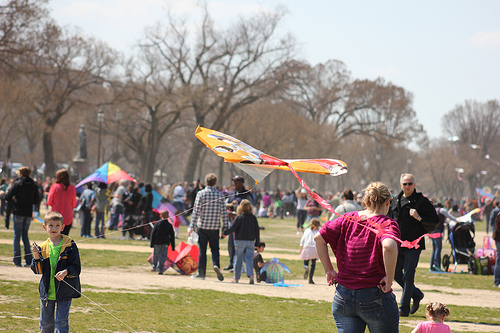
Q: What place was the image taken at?
A: It was taken at the park.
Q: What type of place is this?
A: It is a park.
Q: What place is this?
A: It is a park.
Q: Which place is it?
A: It is a park.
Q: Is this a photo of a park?
A: Yes, it is showing a park.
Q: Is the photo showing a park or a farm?
A: It is showing a park.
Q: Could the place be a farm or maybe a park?
A: It is a park.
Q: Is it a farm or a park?
A: It is a park.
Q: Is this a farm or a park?
A: It is a park.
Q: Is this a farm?
A: No, it is a park.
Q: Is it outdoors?
A: Yes, it is outdoors.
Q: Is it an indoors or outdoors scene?
A: It is outdoors.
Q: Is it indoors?
A: No, it is outdoors.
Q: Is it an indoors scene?
A: No, it is outdoors.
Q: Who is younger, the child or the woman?
A: The child is younger than the woman.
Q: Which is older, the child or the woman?
A: The woman is older than the child.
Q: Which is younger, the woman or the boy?
A: The boy is younger than the woman.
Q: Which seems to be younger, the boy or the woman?
A: The boy is younger than the woman.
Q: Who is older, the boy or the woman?
A: The woman is older than the boy.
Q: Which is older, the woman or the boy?
A: The woman is older than the boy.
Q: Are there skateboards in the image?
A: No, there are no skateboards.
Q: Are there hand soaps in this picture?
A: No, there are no hand soaps.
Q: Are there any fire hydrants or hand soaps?
A: No, there are no hand soaps or fire hydrants.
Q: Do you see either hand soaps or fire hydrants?
A: No, there are no hand soaps or fire hydrants.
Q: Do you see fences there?
A: No, there are no fences.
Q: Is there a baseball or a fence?
A: No, there are no fences or baseballs.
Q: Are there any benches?
A: No, there are no benches.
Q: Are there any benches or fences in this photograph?
A: No, there are no benches or fences.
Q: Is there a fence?
A: No, there are no fences.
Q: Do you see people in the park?
A: Yes, there are people in the park.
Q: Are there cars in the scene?
A: No, there are no cars.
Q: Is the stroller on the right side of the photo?
A: Yes, the stroller is on the right of the image.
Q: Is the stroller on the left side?
A: No, the stroller is on the right of the image.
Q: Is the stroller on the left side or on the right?
A: The stroller is on the right of the image.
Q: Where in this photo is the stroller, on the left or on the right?
A: The stroller is on the right of the image.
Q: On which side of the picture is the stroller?
A: The stroller is on the right of the image.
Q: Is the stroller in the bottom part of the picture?
A: Yes, the stroller is in the bottom of the image.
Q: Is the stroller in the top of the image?
A: No, the stroller is in the bottom of the image.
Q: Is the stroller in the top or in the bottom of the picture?
A: The stroller is in the bottom of the image.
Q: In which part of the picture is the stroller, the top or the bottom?
A: The stroller is in the bottom of the image.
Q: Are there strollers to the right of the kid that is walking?
A: Yes, there is a stroller to the right of the child.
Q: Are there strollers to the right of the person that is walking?
A: Yes, there is a stroller to the right of the child.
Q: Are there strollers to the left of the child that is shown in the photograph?
A: No, the stroller is to the right of the child.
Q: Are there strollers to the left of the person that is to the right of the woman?
A: No, the stroller is to the right of the child.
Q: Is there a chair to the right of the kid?
A: No, there is a stroller to the right of the kid.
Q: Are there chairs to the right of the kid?
A: No, there is a stroller to the right of the kid.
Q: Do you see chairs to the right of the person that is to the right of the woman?
A: No, there is a stroller to the right of the kid.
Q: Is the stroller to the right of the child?
A: Yes, the stroller is to the right of the child.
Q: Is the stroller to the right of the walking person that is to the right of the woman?
A: Yes, the stroller is to the right of the child.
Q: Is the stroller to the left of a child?
A: No, the stroller is to the right of a child.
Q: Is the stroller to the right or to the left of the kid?
A: The stroller is to the right of the kid.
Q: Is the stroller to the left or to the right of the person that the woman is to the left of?
A: The stroller is to the right of the kid.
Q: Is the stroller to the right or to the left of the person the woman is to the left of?
A: The stroller is to the right of the kid.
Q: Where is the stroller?
A: The stroller is in the park.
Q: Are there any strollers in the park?
A: Yes, there is a stroller in the park.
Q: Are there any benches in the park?
A: No, there is a stroller in the park.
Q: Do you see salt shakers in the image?
A: No, there are no salt shakers.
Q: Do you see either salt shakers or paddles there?
A: No, there are no salt shakers or paddles.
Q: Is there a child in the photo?
A: Yes, there is a child.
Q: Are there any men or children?
A: Yes, there is a child.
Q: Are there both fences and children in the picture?
A: No, there is a child but no fences.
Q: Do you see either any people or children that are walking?
A: Yes, the child is walking.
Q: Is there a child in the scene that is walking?
A: Yes, there is a child that is walking.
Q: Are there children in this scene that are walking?
A: Yes, there is a child that is walking.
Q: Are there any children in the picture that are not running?
A: Yes, there is a child that is walking.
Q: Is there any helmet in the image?
A: No, there are no helmets.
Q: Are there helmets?
A: No, there are no helmets.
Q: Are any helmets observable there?
A: No, there are no helmets.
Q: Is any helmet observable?
A: No, there are no helmets.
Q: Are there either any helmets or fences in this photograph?
A: No, there are no helmets or fences.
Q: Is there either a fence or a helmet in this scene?
A: No, there are no helmets or fences.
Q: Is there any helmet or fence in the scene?
A: No, there are no helmets or fences.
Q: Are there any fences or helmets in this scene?
A: No, there are no helmets or fences.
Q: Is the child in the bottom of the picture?
A: Yes, the child is in the bottom of the image.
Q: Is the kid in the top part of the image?
A: No, the kid is in the bottom of the image.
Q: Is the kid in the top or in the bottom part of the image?
A: The kid is in the bottom of the image.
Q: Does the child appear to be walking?
A: Yes, the child is walking.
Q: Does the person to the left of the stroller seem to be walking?
A: Yes, the child is walking.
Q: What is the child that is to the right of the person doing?
A: The child is walking.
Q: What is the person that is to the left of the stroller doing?
A: The child is walking.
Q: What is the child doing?
A: The child is walking.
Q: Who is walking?
A: The child is walking.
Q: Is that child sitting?
A: No, the child is walking.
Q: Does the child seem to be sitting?
A: No, the child is walking.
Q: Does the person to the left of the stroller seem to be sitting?
A: No, the child is walking.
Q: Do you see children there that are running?
A: No, there is a child but he is walking.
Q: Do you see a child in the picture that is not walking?
A: No, there is a child but he is walking.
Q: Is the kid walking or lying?
A: The kid is walking.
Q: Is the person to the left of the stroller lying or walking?
A: The kid is walking.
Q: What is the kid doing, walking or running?
A: The kid is walking.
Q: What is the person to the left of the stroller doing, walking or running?
A: The kid is walking.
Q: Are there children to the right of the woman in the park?
A: Yes, there is a child to the right of the woman.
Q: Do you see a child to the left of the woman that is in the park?
A: No, the child is to the right of the woman.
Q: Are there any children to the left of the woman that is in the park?
A: No, the child is to the right of the woman.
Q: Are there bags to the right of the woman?
A: No, there is a child to the right of the woman.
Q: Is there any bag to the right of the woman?
A: No, there is a child to the right of the woman.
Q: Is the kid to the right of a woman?
A: Yes, the kid is to the right of a woman.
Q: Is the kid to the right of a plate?
A: No, the kid is to the right of a woman.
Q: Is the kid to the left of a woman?
A: No, the kid is to the right of a woman.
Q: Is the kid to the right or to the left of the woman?
A: The kid is to the right of the woman.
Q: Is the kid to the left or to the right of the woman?
A: The kid is to the right of the woman.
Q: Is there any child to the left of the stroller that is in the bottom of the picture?
A: Yes, there is a child to the left of the stroller.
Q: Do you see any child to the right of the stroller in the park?
A: No, the child is to the left of the stroller.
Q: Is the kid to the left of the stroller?
A: Yes, the kid is to the left of the stroller.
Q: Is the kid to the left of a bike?
A: No, the kid is to the left of the stroller.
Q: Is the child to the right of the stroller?
A: No, the child is to the left of the stroller.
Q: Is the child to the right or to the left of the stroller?
A: The child is to the left of the stroller.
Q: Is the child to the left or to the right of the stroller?
A: The child is to the left of the stroller.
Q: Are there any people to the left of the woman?
A: Yes, there is a person to the left of the woman.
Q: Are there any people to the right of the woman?
A: No, the person is to the left of the woman.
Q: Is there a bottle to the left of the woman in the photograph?
A: No, there is a person to the left of the woman.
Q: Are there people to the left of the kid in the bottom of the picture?
A: Yes, there is a person to the left of the kid.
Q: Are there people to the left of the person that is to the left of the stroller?
A: Yes, there is a person to the left of the kid.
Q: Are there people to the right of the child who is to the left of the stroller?
A: No, the person is to the left of the child.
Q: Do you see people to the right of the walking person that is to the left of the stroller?
A: No, the person is to the left of the child.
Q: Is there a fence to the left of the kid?
A: No, there is a person to the left of the kid.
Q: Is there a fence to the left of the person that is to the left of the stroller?
A: No, there is a person to the left of the kid.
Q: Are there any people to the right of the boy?
A: Yes, there is a person to the right of the boy.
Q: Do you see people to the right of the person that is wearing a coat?
A: Yes, there is a person to the right of the boy.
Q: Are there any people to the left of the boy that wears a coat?
A: No, the person is to the right of the boy.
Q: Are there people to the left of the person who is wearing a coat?
A: No, the person is to the right of the boy.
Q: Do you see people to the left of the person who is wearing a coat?
A: No, the person is to the right of the boy.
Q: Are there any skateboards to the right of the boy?
A: No, there is a person to the right of the boy.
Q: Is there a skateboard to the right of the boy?
A: No, there is a person to the right of the boy.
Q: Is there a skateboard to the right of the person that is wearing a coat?
A: No, there is a person to the right of the boy.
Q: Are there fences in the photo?
A: No, there are no fences.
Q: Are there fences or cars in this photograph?
A: No, there are no fences or cars.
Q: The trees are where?
A: The trees are in the park.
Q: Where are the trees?
A: The trees are in the park.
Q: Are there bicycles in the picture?
A: No, there are no bicycles.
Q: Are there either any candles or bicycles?
A: No, there are no bicycles or candles.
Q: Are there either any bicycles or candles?
A: No, there are no bicycles or candles.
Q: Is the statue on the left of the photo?
A: Yes, the statue is on the left of the image.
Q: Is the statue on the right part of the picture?
A: No, the statue is on the left of the image.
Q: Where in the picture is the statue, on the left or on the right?
A: The statue is on the left of the image.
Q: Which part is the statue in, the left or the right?
A: The statue is on the left of the image.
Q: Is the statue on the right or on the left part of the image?
A: The statue is on the left of the image.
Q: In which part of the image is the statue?
A: The statue is on the left of the image.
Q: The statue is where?
A: The statue is in the park.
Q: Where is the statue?
A: The statue is in the park.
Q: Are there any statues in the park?
A: Yes, there is a statue in the park.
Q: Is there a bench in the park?
A: No, there is a statue in the park.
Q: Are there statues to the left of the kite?
A: Yes, there is a statue to the left of the kite.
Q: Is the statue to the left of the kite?
A: Yes, the statue is to the left of the kite.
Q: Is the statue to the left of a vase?
A: No, the statue is to the left of the kite.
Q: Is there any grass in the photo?
A: Yes, there is grass.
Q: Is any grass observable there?
A: Yes, there is grass.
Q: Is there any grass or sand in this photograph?
A: Yes, there is grass.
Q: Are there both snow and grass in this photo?
A: No, there is grass but no snow.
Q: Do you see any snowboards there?
A: No, there are no snowboards.